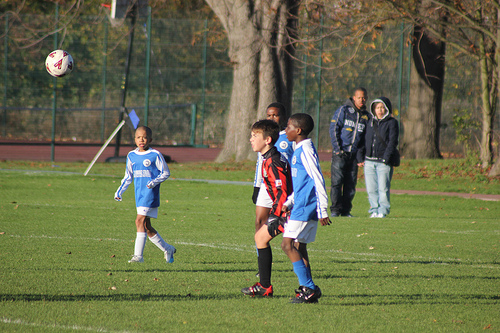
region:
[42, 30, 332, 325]
these kids are playing soccer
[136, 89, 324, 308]
the child dressed in red and black is by himself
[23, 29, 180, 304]
the ball is soaring through the air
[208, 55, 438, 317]
spectators are watching the match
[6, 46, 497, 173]
there is a fence in the background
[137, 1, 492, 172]
tree trunks can be seen in the photo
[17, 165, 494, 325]
the soccer field is green grass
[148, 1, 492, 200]
the season in this picture is fall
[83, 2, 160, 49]
a barely noticeable basketball rim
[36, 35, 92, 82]
the soccer ball is red and white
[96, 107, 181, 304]
Kid in blue and white playing soccer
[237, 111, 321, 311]
Kid in red and black playing soccer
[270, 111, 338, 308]
Kid in blue and white playing soccer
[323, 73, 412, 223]
Two people standing on a field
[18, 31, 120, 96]
Soccer ball in the air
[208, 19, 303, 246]
Brown tree by a field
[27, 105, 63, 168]
Green fence by a field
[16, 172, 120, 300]
Green grass with white stripes on a field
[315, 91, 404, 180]
Black jackets on two people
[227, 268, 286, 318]
Black and red soccer shoes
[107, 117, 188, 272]
Soccer ball in the airBoy in long-sleeved blue jersey standing away from the group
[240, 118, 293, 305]
Boy in red and black jersey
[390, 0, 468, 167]
Large tree with no leaves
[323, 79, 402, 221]
Couple standing at the sidelines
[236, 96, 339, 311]
Group of boys on a field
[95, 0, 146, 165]
Basketball hoop in the background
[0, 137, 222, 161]
Basketball court in the background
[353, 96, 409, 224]
Woman with a hood over her head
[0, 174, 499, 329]
A soccer field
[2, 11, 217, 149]
Tall fence in the background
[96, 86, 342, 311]
four kids playing soccer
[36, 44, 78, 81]
soccer ball high in the air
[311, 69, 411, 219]
two adults standing on the grass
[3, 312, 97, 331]
thin white line painted on the field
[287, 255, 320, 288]
tal blue socks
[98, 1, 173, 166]
basketball hoop on a black pole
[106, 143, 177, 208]
long sleeved blue and white shirt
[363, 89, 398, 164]
hood of the jacket is up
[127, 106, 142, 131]
bright blue flag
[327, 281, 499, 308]
shadow on the soccer field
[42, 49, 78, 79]
Red and white soccer ball.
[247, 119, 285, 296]
Boy in red & black uniform.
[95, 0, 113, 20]
Basketball hoop.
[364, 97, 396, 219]
Woman watching from sidelines.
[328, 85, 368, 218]
Man watching from sidelines.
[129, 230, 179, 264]
Boy's white socks.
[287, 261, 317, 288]
Boy's blue sock.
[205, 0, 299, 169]
Trunk of largest visible tree.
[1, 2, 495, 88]
Wooded area in background.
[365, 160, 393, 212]
Woman's blue jeans.